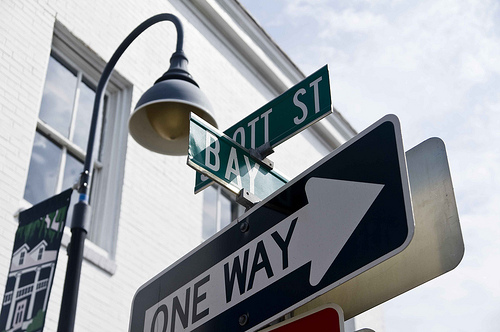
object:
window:
[32, 290, 49, 312]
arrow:
[141, 175, 386, 331]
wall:
[0, 0, 331, 331]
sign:
[187, 111, 291, 205]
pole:
[236, 187, 261, 207]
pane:
[40, 47, 81, 140]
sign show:
[257, 303, 345, 331]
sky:
[235, 0, 497, 330]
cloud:
[236, 1, 500, 330]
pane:
[23, 128, 65, 204]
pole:
[55, 12, 183, 331]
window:
[23, 128, 66, 206]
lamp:
[56, 12, 220, 331]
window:
[18, 252, 26, 259]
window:
[38, 266, 52, 280]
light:
[148, 103, 198, 140]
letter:
[269, 216, 297, 268]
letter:
[246, 238, 273, 289]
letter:
[221, 248, 248, 302]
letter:
[191, 272, 211, 322]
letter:
[168, 285, 190, 331]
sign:
[128, 113, 414, 332]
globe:
[126, 78, 218, 157]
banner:
[0, 187, 74, 331]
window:
[38, 47, 80, 142]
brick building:
[0, 0, 358, 330]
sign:
[193, 62, 330, 194]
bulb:
[152, 102, 191, 141]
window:
[17, 303, 22, 311]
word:
[222, 216, 299, 302]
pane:
[71, 74, 109, 162]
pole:
[230, 203, 241, 222]